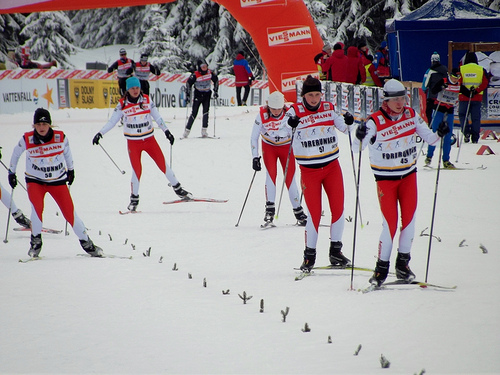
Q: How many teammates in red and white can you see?
A: Five.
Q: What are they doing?
A: Cross country skiing.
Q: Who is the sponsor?
A: Viessmann.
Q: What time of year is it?
A: Winter.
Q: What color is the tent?
A: Blue.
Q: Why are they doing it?
A: They are competing.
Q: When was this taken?
A: During the day.